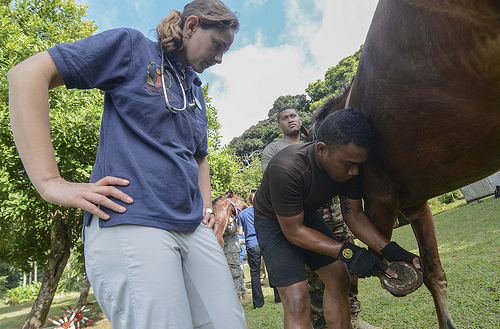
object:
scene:
[1, 0, 499, 328]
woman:
[5, 1, 250, 328]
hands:
[44, 175, 137, 221]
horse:
[296, 0, 500, 326]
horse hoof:
[379, 256, 425, 297]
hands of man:
[335, 242, 400, 282]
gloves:
[336, 241, 389, 281]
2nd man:
[257, 107, 316, 175]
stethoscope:
[157, 34, 195, 116]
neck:
[170, 48, 196, 69]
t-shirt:
[46, 27, 214, 232]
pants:
[81, 212, 244, 328]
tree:
[1, 0, 102, 328]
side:
[333, 0, 500, 191]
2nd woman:
[234, 188, 284, 308]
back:
[237, 207, 256, 244]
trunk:
[24, 207, 82, 328]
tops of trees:
[268, 93, 308, 117]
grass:
[241, 195, 500, 328]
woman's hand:
[43, 174, 135, 220]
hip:
[83, 169, 142, 240]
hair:
[154, 0, 240, 55]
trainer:
[234, 192, 280, 309]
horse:
[209, 191, 249, 250]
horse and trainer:
[210, 188, 264, 312]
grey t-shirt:
[260, 137, 306, 177]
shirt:
[252, 141, 366, 221]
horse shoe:
[380, 261, 423, 294]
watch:
[205, 207, 217, 216]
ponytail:
[155, 7, 182, 54]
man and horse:
[251, 0, 500, 329]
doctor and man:
[4, 0, 429, 329]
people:
[252, 107, 428, 328]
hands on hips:
[42, 173, 136, 232]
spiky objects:
[49, 301, 98, 327]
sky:
[7, 0, 376, 153]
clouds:
[205, 3, 377, 154]